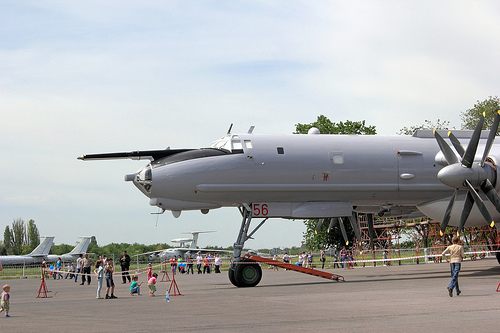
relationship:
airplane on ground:
[77, 121, 499, 289] [10, 249, 496, 324]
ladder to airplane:
[244, 251, 354, 287] [77, 121, 499, 289]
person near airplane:
[439, 228, 471, 298] [77, 121, 499, 289]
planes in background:
[2, 224, 216, 268] [9, 8, 490, 272]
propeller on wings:
[434, 121, 499, 228] [428, 105, 500, 237]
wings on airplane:
[428, 105, 500, 237] [77, 121, 499, 289]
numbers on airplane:
[248, 199, 272, 220] [77, 121, 499, 289]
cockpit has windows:
[208, 129, 265, 193] [215, 135, 256, 158]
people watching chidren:
[86, 261, 117, 303] [123, 273, 159, 293]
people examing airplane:
[46, 241, 225, 272] [77, 121, 499, 289]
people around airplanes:
[46, 241, 225, 272] [6, 111, 499, 281]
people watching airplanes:
[86, 261, 117, 303] [6, 111, 499, 281]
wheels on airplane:
[226, 258, 265, 292] [77, 121, 499, 289]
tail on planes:
[173, 230, 211, 246] [2, 224, 216, 268]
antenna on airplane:
[354, 114, 378, 134] [77, 121, 499, 289]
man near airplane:
[74, 255, 84, 282] [77, 121, 499, 289]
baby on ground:
[0, 281, 13, 320] [10, 249, 496, 324]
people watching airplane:
[86, 261, 117, 303] [77, 121, 499, 289]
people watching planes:
[46, 241, 225, 272] [2, 224, 216, 268]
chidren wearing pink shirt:
[144, 273, 160, 297] [149, 278, 160, 285]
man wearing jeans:
[74, 255, 84, 282] [449, 264, 465, 295]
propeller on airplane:
[434, 121, 499, 228] [77, 121, 499, 289]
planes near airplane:
[2, 224, 216, 268] [77, 121, 499, 289]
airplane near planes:
[77, 121, 499, 289] [2, 224, 216, 268]